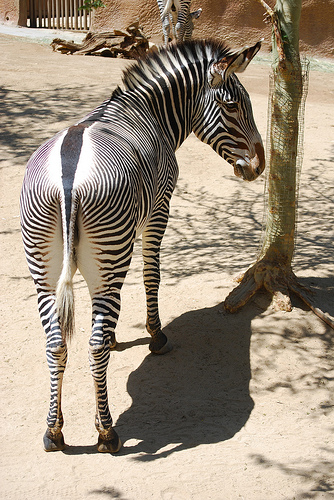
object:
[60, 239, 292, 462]
shadow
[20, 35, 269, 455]
zebra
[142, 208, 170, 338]
leg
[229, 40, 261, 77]
ear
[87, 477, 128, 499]
shadow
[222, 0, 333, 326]
trees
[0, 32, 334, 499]
ground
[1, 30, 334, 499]
dirt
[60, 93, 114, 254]
stripe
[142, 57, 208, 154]
neck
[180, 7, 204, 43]
head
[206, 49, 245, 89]
ears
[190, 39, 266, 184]
head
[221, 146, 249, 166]
stripes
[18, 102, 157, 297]
back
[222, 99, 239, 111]
eye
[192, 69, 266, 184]
face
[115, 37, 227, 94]
hair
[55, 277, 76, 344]
hair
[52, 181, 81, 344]
tail